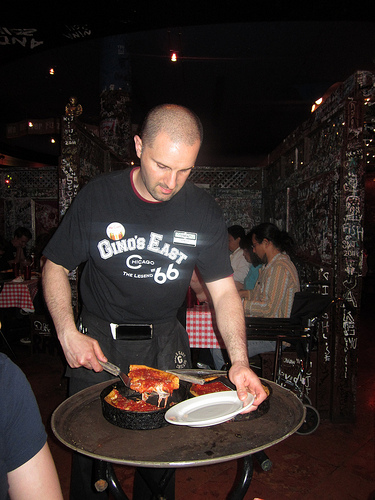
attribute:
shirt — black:
[38, 166, 235, 326]